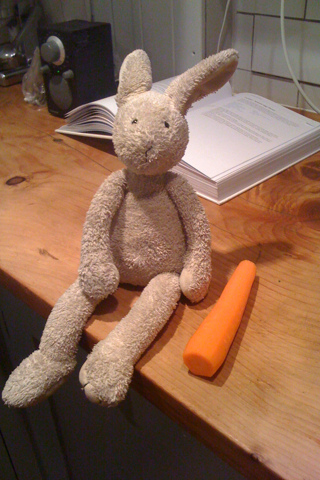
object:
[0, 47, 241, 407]
bunny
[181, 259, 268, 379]
carrot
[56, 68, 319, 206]
book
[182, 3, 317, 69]
wall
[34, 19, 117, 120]
speaker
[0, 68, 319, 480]
table